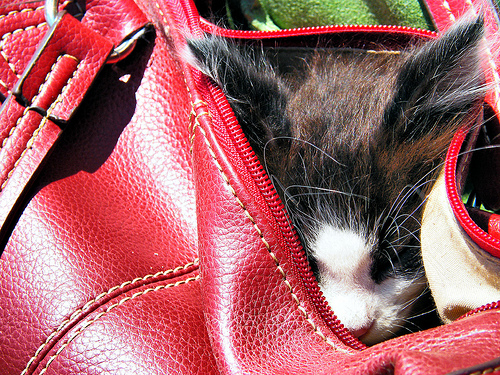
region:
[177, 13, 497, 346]
black brown and white cat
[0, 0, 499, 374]
red purse with a cat in it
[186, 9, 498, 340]
cat hiding inside of a purse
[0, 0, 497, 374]
red leather purse with stitching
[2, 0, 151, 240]
purse handle around a metal ring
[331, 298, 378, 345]
small pink cat nose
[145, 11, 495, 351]
Cat hiding in the purse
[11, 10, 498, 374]
Red leather purse with a cat inside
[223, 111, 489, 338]
White hair on the cat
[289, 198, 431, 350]
White spot on the cat's face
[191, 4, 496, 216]
Dark fur on the cat's head and ears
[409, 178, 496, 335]
inner lining of the purse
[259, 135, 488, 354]
Cat looking down in the purse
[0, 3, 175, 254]
Strap attached to the purse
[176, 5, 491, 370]
Red zipper on the purse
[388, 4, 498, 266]
Other side of the strap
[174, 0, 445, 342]
A cat inside of a purse.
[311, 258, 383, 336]
A nose on a cat.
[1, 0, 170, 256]
A red strap on a purse.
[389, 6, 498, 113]
A left ear on a cat.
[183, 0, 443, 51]
A zipper on a purse.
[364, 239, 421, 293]
A left cat eye.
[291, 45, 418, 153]
The top of a cat head.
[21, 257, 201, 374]
Stitching on a purse.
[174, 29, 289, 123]
A right cat ear.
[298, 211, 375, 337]
The forehead of a cat.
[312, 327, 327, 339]
tan stitch on purse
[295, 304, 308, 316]
tan stitch on purse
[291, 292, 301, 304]
tan stitch on purse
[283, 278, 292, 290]
tan stitch on purse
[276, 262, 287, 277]
tan stitch on purse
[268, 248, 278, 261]
tan stitch on purse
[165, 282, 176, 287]
tan stitch on purse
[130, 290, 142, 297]
tan stitch on purse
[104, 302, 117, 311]
tan stitch on purse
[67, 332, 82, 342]
tan stitch on purse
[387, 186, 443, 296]
the whiskers are white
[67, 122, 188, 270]
the bag is leather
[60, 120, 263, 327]
the bag is red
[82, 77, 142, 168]
shadow of the strap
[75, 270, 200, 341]
the seams are golden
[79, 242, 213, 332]
stitching on the bag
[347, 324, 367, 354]
the nose is pink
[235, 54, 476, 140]
the ears are black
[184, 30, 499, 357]
the bag is open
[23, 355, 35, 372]
white stitch on purse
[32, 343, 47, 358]
white stitch on purse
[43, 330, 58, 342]
white stitch on purse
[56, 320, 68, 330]
white stitch on purse